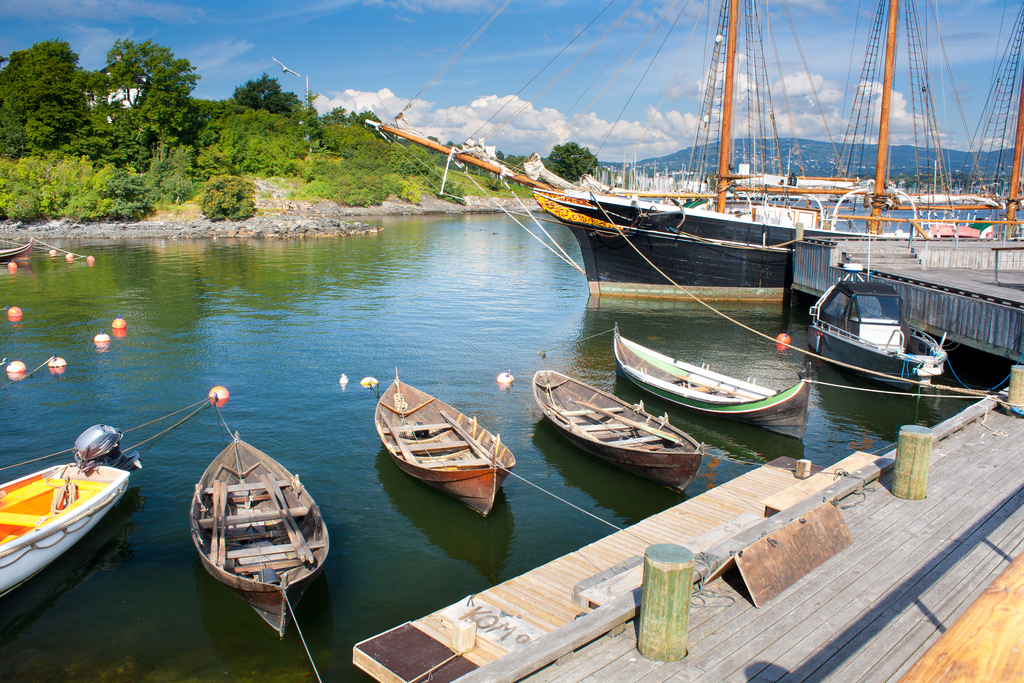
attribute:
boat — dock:
[588, 186, 730, 283]